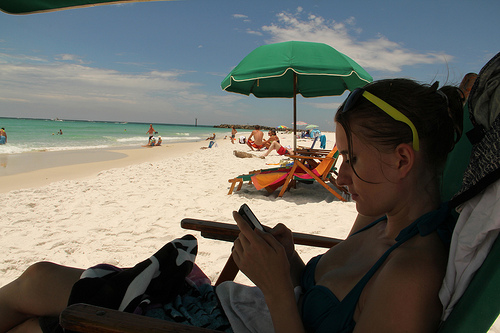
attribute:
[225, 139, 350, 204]
chair — orange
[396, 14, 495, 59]
sky — blue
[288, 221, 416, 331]
bikini — black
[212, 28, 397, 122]
umbrella — green